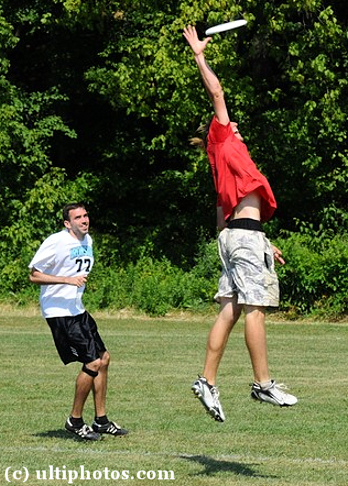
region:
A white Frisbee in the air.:
[202, 16, 256, 37]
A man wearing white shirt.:
[32, 195, 141, 439]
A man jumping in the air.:
[183, 81, 294, 422]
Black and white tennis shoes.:
[63, 406, 125, 444]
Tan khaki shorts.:
[210, 226, 288, 315]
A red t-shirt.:
[197, 120, 279, 214]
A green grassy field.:
[8, 315, 334, 484]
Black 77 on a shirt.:
[70, 257, 95, 275]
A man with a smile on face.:
[53, 203, 101, 239]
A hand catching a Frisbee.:
[180, 24, 211, 52]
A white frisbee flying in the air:
[202, 16, 251, 36]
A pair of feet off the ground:
[182, 367, 310, 429]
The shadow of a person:
[174, 446, 281, 482]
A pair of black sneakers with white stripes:
[62, 406, 131, 442]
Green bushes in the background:
[122, 249, 194, 318]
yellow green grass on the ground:
[121, 327, 189, 367]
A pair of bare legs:
[196, 301, 269, 377]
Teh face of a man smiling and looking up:
[60, 201, 94, 236]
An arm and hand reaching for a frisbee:
[177, 10, 255, 97]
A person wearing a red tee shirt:
[203, 115, 293, 212]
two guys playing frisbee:
[26, 11, 325, 456]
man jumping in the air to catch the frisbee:
[162, 11, 319, 448]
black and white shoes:
[53, 412, 144, 451]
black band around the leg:
[73, 363, 98, 382]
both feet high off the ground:
[186, 354, 324, 433]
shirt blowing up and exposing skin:
[217, 166, 285, 235]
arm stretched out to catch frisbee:
[179, 19, 248, 126]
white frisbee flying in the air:
[199, 8, 260, 40]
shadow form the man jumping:
[156, 434, 282, 484]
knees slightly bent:
[63, 333, 126, 380]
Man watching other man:
[33, 193, 141, 440]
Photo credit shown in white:
[1, 470, 196, 482]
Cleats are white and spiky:
[185, 368, 307, 419]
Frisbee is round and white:
[202, 16, 251, 38]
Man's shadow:
[180, 446, 256, 483]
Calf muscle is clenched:
[196, 310, 240, 361]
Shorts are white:
[205, 230, 282, 314]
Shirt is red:
[199, 123, 275, 203]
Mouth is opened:
[231, 127, 243, 136]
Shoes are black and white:
[61, 417, 139, 444]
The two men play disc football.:
[35, 109, 292, 356]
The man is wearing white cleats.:
[186, 362, 308, 424]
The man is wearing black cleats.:
[62, 412, 135, 443]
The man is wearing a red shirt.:
[208, 121, 272, 198]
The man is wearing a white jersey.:
[34, 235, 103, 317]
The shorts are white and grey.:
[216, 226, 293, 311]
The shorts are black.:
[50, 316, 110, 362]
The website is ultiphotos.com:
[8, 455, 178, 484]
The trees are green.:
[55, 26, 186, 119]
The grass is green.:
[127, 338, 171, 374]